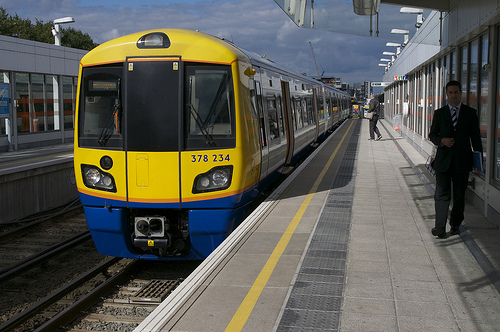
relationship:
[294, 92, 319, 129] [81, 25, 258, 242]
glass on train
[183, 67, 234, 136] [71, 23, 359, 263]
window of a train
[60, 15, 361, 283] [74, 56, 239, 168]
train has window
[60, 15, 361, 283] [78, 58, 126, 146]
train has window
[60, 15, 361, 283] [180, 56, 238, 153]
train has window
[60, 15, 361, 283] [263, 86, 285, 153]
train has window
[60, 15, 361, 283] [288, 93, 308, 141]
train has window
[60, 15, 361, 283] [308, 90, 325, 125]
train has window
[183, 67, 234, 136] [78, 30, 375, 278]
window on front of train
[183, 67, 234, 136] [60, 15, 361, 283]
window on train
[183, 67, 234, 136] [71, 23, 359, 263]
window on train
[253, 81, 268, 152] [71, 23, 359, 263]
window on train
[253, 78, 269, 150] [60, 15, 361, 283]
window of train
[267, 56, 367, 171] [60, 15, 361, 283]
window on train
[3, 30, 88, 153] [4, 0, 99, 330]
building to left